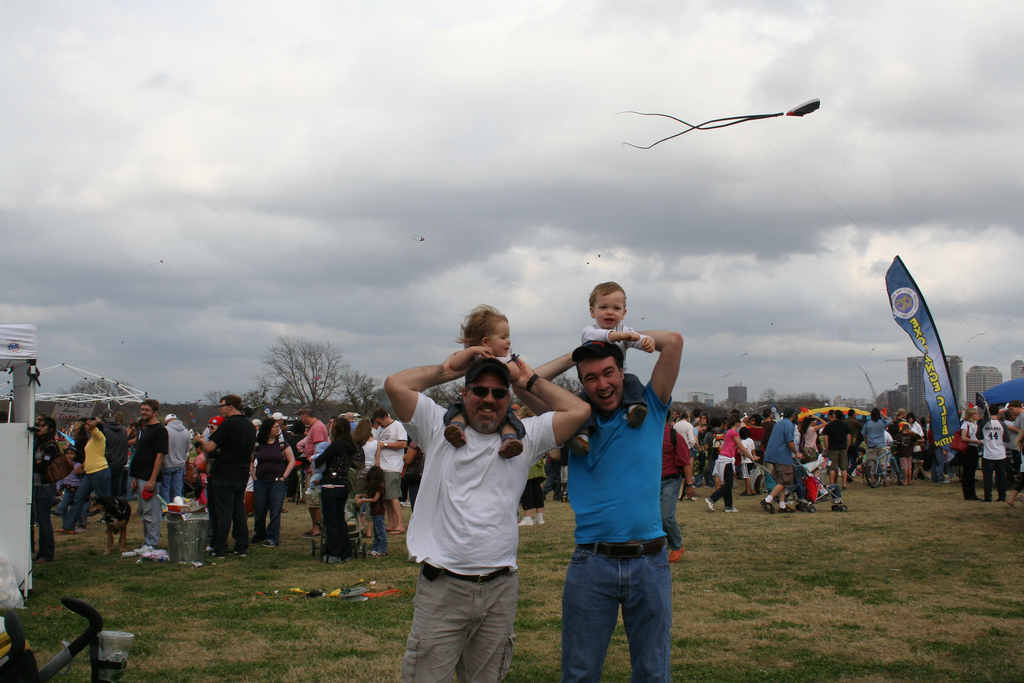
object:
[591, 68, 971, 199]
kite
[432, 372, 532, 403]
sunglasses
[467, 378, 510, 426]
face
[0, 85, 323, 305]
clouds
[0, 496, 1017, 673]
grass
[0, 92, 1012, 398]
sky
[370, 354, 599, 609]
man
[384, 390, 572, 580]
shirt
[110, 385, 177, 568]
man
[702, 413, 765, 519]
woman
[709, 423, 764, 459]
shirt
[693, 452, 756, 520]
pants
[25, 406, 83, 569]
woman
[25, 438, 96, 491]
bag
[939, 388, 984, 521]
woman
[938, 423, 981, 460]
bag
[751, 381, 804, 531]
man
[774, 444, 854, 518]
baby carriage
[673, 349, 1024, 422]
buildings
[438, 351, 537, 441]
head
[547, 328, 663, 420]
head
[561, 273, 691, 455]
person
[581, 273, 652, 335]
head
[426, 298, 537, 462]
person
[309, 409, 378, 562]
person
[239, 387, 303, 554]
person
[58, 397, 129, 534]
person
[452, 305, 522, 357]
head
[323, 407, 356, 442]
head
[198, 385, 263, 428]
head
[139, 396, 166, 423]
head